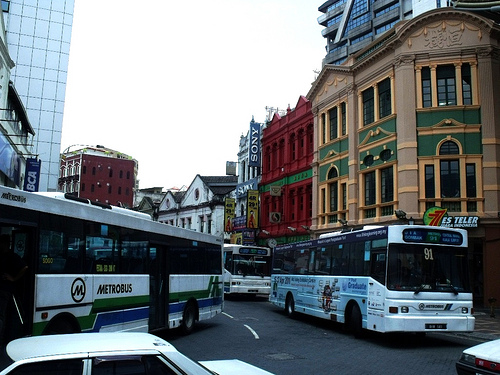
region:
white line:
[235, 312, 282, 353]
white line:
[221, 307, 266, 358]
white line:
[225, 311, 295, 369]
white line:
[238, 290, 263, 341]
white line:
[232, 312, 264, 342]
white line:
[210, 275, 280, 357]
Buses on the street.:
[58, 207, 470, 339]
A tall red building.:
[246, 110, 316, 246]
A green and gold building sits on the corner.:
[311, 75, 498, 225]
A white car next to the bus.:
[61, 303, 273, 373]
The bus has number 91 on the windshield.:
[418, 242, 435, 270]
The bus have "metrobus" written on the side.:
[97, 278, 174, 302]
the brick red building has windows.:
[56, 120, 156, 224]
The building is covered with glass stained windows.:
[16, 6, 72, 162]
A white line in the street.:
[236, 309, 270, 362]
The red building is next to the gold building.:
[260, 93, 463, 217]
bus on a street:
[258, 219, 486, 344]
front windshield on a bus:
[383, 239, 475, 300]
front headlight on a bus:
[456, 301, 475, 318]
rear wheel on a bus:
[280, 287, 302, 321]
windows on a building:
[411, 51, 483, 116]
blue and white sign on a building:
[243, 117, 265, 172]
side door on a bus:
[141, 224, 175, 336]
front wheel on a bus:
[338, 296, 368, 343]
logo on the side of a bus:
[66, 276, 91, 306]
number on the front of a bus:
[421, 244, 436, 264]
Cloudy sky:
[152, 23, 253, 88]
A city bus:
[265, 212, 475, 344]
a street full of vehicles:
[210, 310, 325, 360]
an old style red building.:
[266, 110, 308, 225]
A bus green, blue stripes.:
[5, 197, 215, 333]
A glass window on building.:
[21, 10, 57, 92]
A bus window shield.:
[390, 245, 452, 285]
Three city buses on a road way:
[21, 185, 358, 332]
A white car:
[66, 321, 231, 371]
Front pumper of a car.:
[452, 361, 468, 372]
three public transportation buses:
[0, 218, 475, 330]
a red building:
[261, 92, 318, 254]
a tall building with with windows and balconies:
[301, 2, 391, 57]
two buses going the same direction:
[229, 230, 427, 334]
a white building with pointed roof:
[153, 163, 226, 233]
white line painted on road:
[231, 316, 266, 363]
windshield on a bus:
[361, 230, 473, 308]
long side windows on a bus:
[6, 195, 231, 278]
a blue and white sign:
[244, 111, 266, 182]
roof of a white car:
[0, 322, 245, 367]